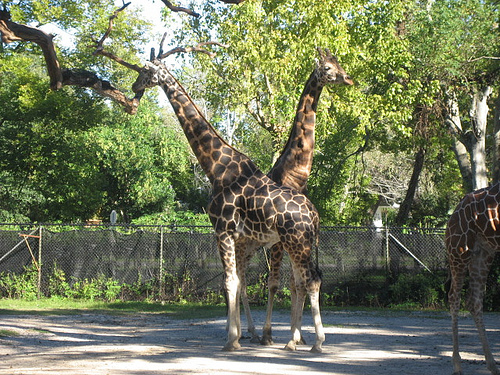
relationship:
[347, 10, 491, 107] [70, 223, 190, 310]
tree near fence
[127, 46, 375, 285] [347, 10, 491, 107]
giraffes near tree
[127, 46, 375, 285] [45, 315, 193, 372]
giraffes on ground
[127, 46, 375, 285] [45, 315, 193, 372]
giraffes in ground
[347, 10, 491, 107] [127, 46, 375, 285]
tree behind giraffes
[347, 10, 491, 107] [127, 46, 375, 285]
tree above giraffes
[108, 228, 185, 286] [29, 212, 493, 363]
metal fencing post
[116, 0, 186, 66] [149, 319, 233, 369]
sunlight shines on ground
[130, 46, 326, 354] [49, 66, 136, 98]
giraffes touching branch